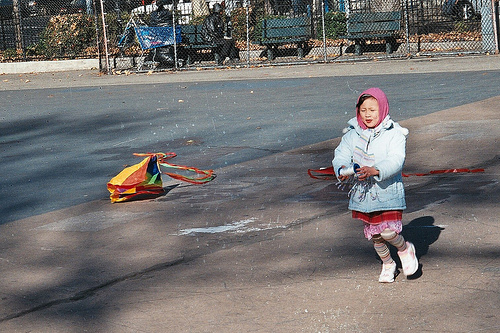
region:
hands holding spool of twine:
[334, 158, 386, 189]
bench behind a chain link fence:
[341, 6, 406, 58]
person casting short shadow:
[338, 86, 443, 285]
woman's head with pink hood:
[352, 86, 392, 135]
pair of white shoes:
[375, 243, 418, 282]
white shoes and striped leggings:
[361, 223, 418, 284]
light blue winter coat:
[333, 116, 407, 211]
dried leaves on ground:
[108, 65, 216, 79]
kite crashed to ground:
[103, 142, 216, 210]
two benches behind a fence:
[248, 1, 414, 62]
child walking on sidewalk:
[324, 82, 436, 286]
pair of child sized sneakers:
[368, 240, 427, 288]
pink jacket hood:
[338, 87, 396, 130]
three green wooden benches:
[141, 5, 416, 56]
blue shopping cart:
[122, 13, 188, 75]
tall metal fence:
[2, 3, 499, 76]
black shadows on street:
[3, 99, 274, 329]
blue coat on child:
[332, 113, 411, 216]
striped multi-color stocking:
[368, 228, 410, 268]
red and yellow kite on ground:
[100, 135, 219, 212]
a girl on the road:
[129, 37, 494, 290]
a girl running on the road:
[128, 53, 493, 330]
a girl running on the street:
[96, 37, 496, 322]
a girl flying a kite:
[114, 48, 497, 308]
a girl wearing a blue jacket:
[322, 44, 447, 301]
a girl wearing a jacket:
[289, 88, 450, 263]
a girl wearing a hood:
[317, 51, 454, 265]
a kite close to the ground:
[37, 91, 270, 290]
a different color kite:
[73, 82, 275, 309]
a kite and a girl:
[37, 62, 497, 294]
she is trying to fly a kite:
[60, 78, 483, 285]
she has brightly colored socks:
[364, 229, 427, 263]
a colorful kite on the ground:
[93, 137, 218, 219]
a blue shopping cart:
[107, 15, 204, 75]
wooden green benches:
[108, 5, 403, 72]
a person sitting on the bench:
[190, 0, 252, 72]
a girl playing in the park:
[113, 38, 449, 305]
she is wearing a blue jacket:
[308, 110, 431, 225]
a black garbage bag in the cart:
[140, 3, 177, 26]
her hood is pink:
[342, 85, 398, 131]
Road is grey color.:
[206, 92, 318, 162]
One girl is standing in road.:
[326, 65, 453, 300]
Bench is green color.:
[142, 10, 437, 65]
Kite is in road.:
[89, 148, 259, 251]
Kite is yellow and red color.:
[77, 144, 225, 226]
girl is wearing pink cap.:
[350, 78, 438, 143]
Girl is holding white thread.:
[303, 134, 378, 209]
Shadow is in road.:
[18, 108, 280, 326]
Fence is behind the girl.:
[4, 10, 498, 67]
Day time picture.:
[8, 29, 448, 298]